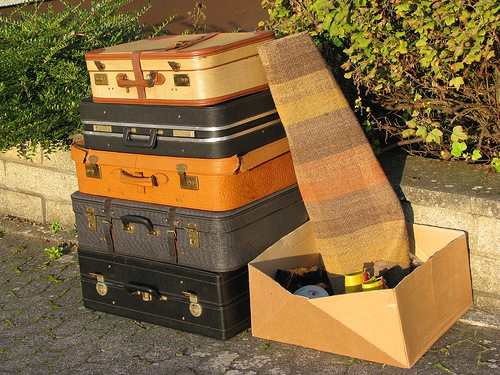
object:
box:
[248, 217, 473, 368]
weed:
[45, 244, 64, 259]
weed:
[49, 221, 62, 233]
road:
[2, 222, 499, 372]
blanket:
[255, 29, 412, 293]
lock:
[184, 221, 200, 250]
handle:
[125, 281, 160, 302]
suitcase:
[71, 142, 298, 213]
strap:
[134, 33, 220, 101]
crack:
[16, 254, 33, 274]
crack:
[47, 314, 69, 334]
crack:
[49, 286, 72, 305]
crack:
[95, 322, 120, 341]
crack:
[4, 337, 24, 354]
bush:
[2, 1, 205, 152]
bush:
[259, 0, 500, 166]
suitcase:
[85, 29, 278, 100]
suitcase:
[80, 89, 287, 159]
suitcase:
[72, 192, 310, 272]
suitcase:
[76, 244, 251, 339]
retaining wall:
[5, 133, 498, 320]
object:
[343, 267, 389, 296]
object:
[294, 284, 328, 300]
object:
[274, 265, 321, 292]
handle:
[119, 213, 156, 234]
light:
[188, 55, 213, 105]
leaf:
[45, 149, 56, 153]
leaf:
[16, 152, 26, 160]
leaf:
[61, 146, 67, 151]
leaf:
[69, 29, 79, 39]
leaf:
[32, 35, 38, 45]